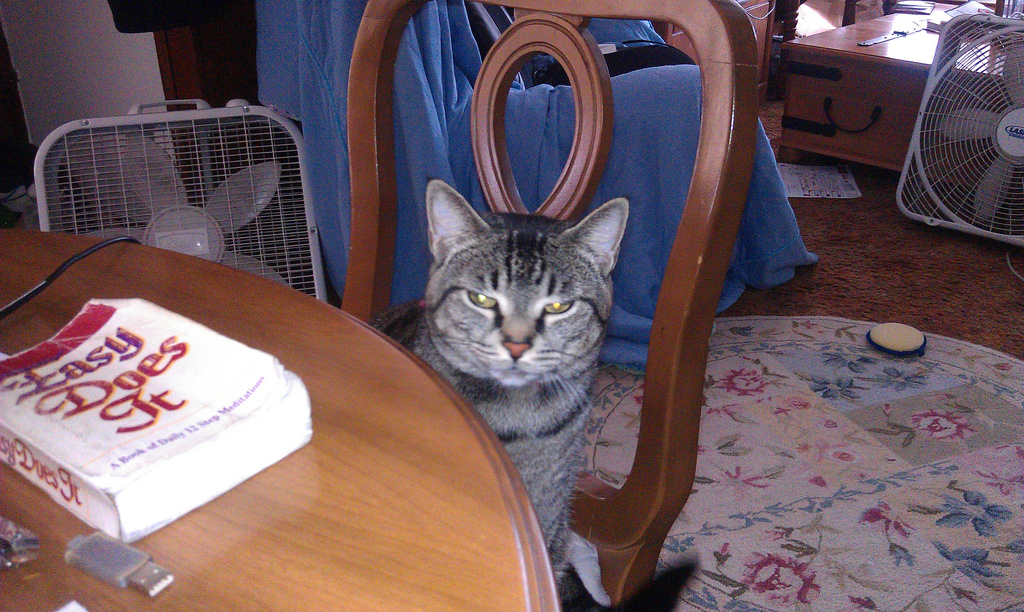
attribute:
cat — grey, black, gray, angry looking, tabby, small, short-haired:
[372, 178, 698, 611]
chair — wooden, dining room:
[341, 2, 761, 611]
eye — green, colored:
[467, 290, 499, 311]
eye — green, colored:
[541, 296, 576, 316]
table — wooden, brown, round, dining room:
[1, 229, 561, 611]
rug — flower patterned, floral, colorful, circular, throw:
[580, 314, 1022, 611]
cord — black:
[0, 233, 139, 316]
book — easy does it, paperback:
[0, 297, 314, 545]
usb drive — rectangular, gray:
[64, 533, 177, 597]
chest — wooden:
[778, 12, 1022, 193]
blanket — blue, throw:
[254, 0, 817, 367]